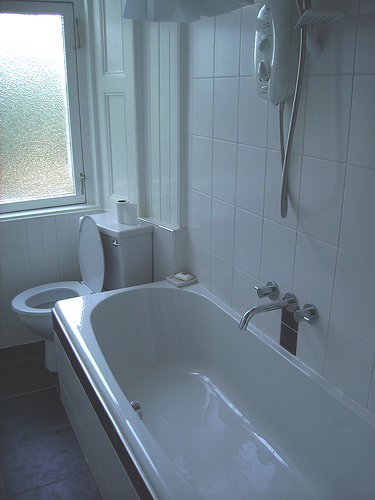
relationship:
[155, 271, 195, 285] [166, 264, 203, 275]
bar of soap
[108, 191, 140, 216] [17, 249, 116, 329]
paper by toilet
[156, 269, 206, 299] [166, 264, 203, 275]
dish for soap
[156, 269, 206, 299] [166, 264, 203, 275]
dish has soap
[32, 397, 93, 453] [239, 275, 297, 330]
tile along tub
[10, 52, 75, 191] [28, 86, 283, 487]
window in bathroom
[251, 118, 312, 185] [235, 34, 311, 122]
cord for shower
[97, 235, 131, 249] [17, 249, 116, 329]
handle on toilet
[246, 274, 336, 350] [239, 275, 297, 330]
fixtures in tub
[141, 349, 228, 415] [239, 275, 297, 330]
reflection in tub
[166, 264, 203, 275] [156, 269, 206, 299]
soap on dish